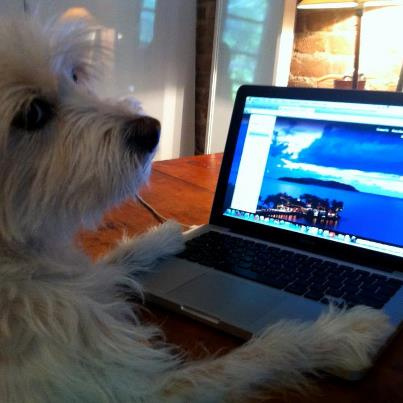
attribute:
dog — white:
[17, 60, 174, 363]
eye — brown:
[11, 90, 62, 151]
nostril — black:
[126, 131, 152, 154]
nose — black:
[117, 93, 180, 174]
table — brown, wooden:
[61, 137, 395, 379]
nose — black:
[120, 107, 167, 157]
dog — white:
[2, 8, 387, 400]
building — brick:
[259, 7, 401, 83]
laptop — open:
[163, 73, 382, 337]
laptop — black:
[130, 75, 400, 373]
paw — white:
[121, 216, 190, 268]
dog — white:
[18, 22, 163, 296]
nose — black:
[119, 113, 163, 155]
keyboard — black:
[170, 214, 400, 311]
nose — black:
[129, 113, 160, 159]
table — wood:
[153, 162, 207, 219]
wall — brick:
[278, 1, 401, 100]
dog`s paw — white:
[282, 299, 393, 374]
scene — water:
[280, 137, 392, 199]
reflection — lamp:
[47, 5, 118, 79]